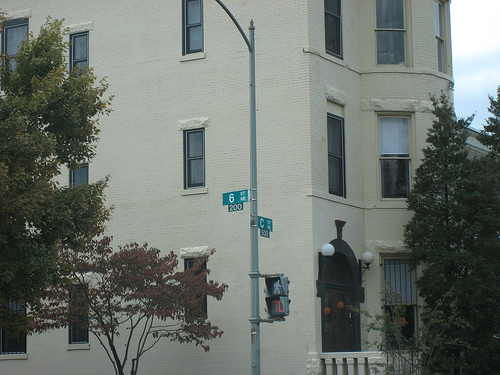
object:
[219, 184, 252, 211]
sign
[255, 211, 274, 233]
sign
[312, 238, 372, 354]
doorway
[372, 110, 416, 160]
blind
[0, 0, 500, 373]
building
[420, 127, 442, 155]
ground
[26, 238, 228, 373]
tree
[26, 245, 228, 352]
foliage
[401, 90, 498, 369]
leaves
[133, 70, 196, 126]
wall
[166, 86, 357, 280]
wall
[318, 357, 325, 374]
pillar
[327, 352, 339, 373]
pillar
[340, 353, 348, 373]
pillar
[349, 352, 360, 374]
pillar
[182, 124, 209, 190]
window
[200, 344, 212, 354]
bloom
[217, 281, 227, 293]
bloom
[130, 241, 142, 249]
bloom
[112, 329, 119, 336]
bloom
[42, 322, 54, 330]
bloom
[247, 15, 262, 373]
pole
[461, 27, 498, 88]
sky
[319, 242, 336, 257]
light globe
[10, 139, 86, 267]
tree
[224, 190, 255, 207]
lettering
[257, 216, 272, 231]
lettering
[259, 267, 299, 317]
traffic sign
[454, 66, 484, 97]
cloud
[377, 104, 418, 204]
window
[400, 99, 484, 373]
tree